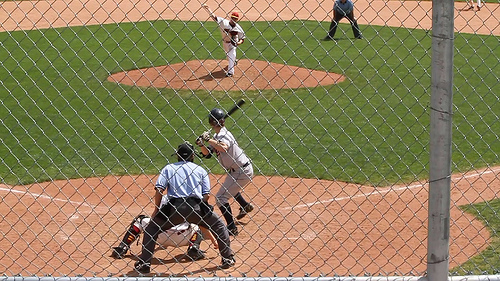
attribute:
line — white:
[268, 149, 498, 226]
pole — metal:
[437, 0, 452, 272]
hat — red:
[230, 9, 239, 19]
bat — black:
[189, 97, 244, 154]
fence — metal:
[0, 2, 499, 280]